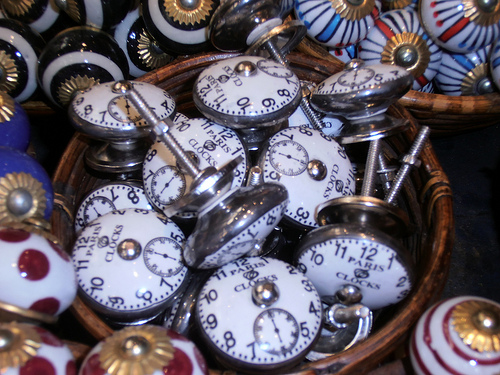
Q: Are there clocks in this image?
A: Yes, there is a clock.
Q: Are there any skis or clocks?
A: Yes, there is a clock.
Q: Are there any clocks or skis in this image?
A: Yes, there is a clock.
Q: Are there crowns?
A: No, there are no crowns.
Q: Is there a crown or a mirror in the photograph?
A: No, there are no crowns or mirrors.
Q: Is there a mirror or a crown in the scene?
A: No, there are no crowns or mirrors.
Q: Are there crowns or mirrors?
A: No, there are no crowns or mirrors.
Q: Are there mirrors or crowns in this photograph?
A: No, there are no crowns or mirrors.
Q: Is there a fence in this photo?
A: No, there are no fences.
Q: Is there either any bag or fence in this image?
A: No, there are no fences or bags.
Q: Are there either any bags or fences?
A: No, there are no fences or bags.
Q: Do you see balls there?
A: Yes, there is a ball.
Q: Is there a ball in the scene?
A: Yes, there is a ball.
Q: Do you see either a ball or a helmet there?
A: Yes, there is a ball.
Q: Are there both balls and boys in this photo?
A: No, there is a ball but no boys.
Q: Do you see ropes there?
A: No, there are no ropes.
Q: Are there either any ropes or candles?
A: No, there are no ropes or candles.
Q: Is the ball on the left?
A: Yes, the ball is on the left of the image.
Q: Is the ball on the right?
A: No, the ball is on the left of the image.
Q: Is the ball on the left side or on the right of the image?
A: The ball is on the left of the image.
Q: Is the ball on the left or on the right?
A: The ball is on the left of the image.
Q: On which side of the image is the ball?
A: The ball is on the left of the image.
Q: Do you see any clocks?
A: Yes, there is a clock.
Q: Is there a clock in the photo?
A: Yes, there is a clock.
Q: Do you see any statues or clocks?
A: Yes, there is a clock.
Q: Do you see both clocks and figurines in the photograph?
A: No, there is a clock but no figurines.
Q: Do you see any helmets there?
A: No, there are no helmets.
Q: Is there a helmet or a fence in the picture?
A: No, there are no helmets or fences.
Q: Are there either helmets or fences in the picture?
A: No, there are no helmets or fences.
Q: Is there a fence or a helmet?
A: No, there are no helmets or fences.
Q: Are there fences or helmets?
A: No, there are no helmets or fences.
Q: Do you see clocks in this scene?
A: Yes, there is a clock.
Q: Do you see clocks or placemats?
A: Yes, there is a clock.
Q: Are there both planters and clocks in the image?
A: No, there is a clock but no planters.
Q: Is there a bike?
A: No, there are no bikes.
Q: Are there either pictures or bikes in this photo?
A: No, there are no bikes or pictures.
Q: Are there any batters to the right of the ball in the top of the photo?
A: No, there is a clock to the right of the ball.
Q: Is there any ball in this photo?
A: Yes, there is a ball.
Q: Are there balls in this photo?
A: Yes, there is a ball.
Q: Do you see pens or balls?
A: Yes, there is a ball.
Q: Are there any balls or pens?
A: Yes, there is a ball.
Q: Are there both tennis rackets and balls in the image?
A: No, there is a ball but no rackets.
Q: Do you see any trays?
A: No, there are no trays.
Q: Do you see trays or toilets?
A: No, there are no trays or toilets.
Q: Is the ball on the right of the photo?
A: No, the ball is on the left of the image.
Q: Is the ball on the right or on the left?
A: The ball is on the left of the image.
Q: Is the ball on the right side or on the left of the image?
A: The ball is on the left of the image.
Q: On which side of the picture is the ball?
A: The ball is on the left of the image.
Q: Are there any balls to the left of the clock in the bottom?
A: Yes, there is a ball to the left of the clock.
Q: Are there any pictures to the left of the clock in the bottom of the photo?
A: No, there is a ball to the left of the clock.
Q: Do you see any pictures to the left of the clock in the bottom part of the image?
A: No, there is a ball to the left of the clock.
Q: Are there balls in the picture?
A: Yes, there is a ball.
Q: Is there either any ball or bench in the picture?
A: Yes, there is a ball.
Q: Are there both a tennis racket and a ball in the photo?
A: No, there is a ball but no rackets.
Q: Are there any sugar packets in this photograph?
A: No, there are no sugar packets.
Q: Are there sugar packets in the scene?
A: No, there are no sugar packets.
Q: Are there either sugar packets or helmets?
A: No, there are no sugar packets or helmets.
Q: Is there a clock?
A: Yes, there is a clock.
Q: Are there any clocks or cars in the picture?
A: Yes, there is a clock.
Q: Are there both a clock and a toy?
A: No, there is a clock but no toys.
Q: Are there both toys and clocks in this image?
A: No, there is a clock but no toys.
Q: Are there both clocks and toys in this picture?
A: No, there is a clock but no toys.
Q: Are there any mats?
A: No, there are no mats.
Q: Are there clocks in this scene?
A: Yes, there is a clock.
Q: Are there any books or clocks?
A: Yes, there is a clock.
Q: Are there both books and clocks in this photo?
A: No, there is a clock but no books.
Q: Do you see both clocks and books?
A: No, there is a clock but no books.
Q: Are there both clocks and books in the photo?
A: No, there is a clock but no books.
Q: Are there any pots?
A: No, there are no pots.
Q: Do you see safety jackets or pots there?
A: No, there are no pots or safety jackets.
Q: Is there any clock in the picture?
A: Yes, there is a clock.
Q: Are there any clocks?
A: Yes, there is a clock.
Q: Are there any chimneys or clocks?
A: Yes, there is a clock.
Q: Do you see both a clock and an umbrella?
A: No, there is a clock but no umbrellas.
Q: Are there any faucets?
A: No, there are no faucets.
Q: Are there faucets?
A: No, there are no faucets.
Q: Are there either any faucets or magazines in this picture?
A: No, there are no faucets or magazines.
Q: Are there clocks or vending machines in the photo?
A: Yes, there is a clock.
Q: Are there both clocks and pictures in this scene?
A: No, there is a clock but no pictures.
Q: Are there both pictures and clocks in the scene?
A: No, there is a clock but no pictures.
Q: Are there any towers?
A: No, there are no towers.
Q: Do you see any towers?
A: No, there are no towers.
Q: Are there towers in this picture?
A: No, there are no towers.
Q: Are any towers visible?
A: No, there are no towers.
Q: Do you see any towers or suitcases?
A: No, there are no towers or suitcases.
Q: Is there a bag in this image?
A: No, there are no bags.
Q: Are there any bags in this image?
A: No, there are no bags.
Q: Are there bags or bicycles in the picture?
A: No, there are no bags or bicycles.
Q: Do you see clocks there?
A: Yes, there is a clock.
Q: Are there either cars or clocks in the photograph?
A: Yes, there is a clock.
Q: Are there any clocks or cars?
A: Yes, there is a clock.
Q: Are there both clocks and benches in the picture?
A: No, there is a clock but no benches.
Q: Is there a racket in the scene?
A: No, there are no rackets.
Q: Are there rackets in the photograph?
A: No, there are no rackets.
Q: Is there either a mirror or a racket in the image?
A: No, there are no rackets or mirrors.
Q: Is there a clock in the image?
A: Yes, there is a clock.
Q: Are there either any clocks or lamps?
A: Yes, there is a clock.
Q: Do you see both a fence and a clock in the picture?
A: No, there is a clock but no fences.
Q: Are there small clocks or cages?
A: Yes, there is a small clock.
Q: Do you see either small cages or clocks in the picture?
A: Yes, there is a small clock.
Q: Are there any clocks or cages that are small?
A: Yes, the clock is small.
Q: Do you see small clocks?
A: Yes, there is a small clock.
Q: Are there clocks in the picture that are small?
A: Yes, there is a clock that is small.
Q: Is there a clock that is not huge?
A: Yes, there is a small clock.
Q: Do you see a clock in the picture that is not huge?
A: Yes, there is a small clock.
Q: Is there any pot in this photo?
A: No, there are no pots.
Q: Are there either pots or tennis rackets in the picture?
A: No, there are no pots or tennis rackets.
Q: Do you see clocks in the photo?
A: Yes, there is a clock.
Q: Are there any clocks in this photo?
A: Yes, there is a clock.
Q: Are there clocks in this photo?
A: Yes, there is a clock.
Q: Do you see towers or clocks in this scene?
A: Yes, there is a clock.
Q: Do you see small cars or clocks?
A: Yes, there is a small clock.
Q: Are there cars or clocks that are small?
A: Yes, the clock is small.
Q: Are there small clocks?
A: Yes, there is a small clock.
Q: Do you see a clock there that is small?
A: Yes, there is a clock that is small.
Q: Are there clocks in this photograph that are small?
A: Yes, there is a clock that is small.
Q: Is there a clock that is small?
A: Yes, there is a clock that is small.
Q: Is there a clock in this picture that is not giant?
A: Yes, there is a small clock.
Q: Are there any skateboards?
A: No, there are no skateboards.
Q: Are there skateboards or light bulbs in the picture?
A: No, there are no skateboards or light bulbs.